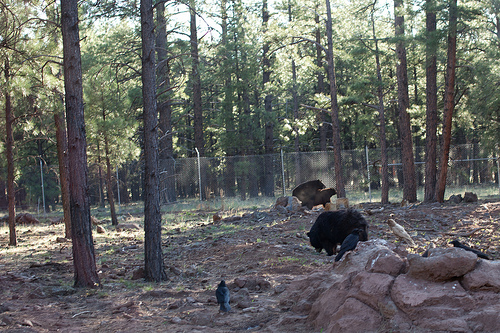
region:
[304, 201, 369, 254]
it is bear in the forest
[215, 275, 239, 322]
it is crow seating in ground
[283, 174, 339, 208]
two bears are visible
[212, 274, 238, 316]
crow color is white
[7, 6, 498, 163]
it is big forest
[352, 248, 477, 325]
it is a stone in the forest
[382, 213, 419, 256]
it is white bird seating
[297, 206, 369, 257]
it is black color bear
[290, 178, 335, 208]
two brown bears in background having sex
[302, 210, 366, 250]
a black bear in the foreground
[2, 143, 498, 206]
a long metal fence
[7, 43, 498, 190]
a forest of tries behind the fence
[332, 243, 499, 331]
a stack of rocks on the right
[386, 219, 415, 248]
a tan bird on the rocks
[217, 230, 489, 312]
three black crows on the ground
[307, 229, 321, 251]
the black bear's head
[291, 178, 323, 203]
the male brown bear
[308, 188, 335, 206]
the female brown bear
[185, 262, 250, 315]
this is a bird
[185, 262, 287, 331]
a bird standing on the ground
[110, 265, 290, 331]
dirt on the ground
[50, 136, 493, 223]
metal fence in background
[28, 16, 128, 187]
sparse leafs on tree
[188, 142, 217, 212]
a pole for fence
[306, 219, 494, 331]
a pile of rocks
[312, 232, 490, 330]
pile of rocks are brown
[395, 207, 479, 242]
a stick on the ground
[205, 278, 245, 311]
A small bird on the ground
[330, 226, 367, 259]
A small bird on the ground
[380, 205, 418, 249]
A small bird on the ground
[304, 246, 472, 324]
A big brown stone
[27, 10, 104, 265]
A tall tree stem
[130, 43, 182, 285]
A tall tree stem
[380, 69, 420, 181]
A tall tree stem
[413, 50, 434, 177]
A tall tree stem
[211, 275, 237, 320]
a bird on the ground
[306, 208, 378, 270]
a bird and a bear are on the ground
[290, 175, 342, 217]
two brown bears are interacting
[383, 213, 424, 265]
a bird is perched on a rock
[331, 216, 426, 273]
two birds perched on a rock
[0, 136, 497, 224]
a tall metal fence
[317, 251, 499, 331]
a large boulder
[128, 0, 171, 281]
a large tree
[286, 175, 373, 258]
three bears on the ground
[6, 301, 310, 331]
brown dirt and rock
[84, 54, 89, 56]
A green leaf on a plant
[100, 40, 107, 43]
A green leaf on a plant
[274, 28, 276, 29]
A green leaf on a plant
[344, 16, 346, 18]
A green leaf on a plant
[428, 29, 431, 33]
A green leaf on a plant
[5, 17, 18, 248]
a tree in a field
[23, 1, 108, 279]
a tree in a field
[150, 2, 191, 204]
a tree in a field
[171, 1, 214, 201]
a tree in a field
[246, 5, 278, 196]
a tree in a field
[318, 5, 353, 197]
a tree in a field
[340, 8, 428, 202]
a tree in a field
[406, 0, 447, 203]
a tree in a field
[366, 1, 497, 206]
a tree in a field